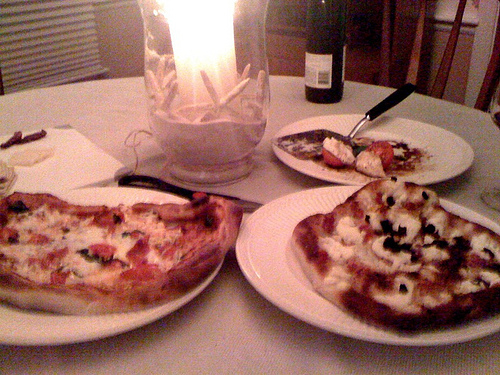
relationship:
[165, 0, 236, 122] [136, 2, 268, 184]
candle in jar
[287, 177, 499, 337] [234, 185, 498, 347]
pizza on plate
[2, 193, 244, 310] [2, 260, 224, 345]
pizza on plate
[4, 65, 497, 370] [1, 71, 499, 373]
table covered with cloth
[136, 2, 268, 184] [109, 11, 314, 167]
jar with starvish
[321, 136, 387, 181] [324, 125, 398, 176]
shells with pastry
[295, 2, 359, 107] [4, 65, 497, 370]
bottle on table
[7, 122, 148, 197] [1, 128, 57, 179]
plate with appetizers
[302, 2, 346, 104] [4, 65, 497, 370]
bottle on table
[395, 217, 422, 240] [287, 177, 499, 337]
feta cheese on pizza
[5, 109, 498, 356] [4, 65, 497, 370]
three plates in table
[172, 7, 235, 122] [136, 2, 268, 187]
candle in jar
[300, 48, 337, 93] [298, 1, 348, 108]
sticker in bottle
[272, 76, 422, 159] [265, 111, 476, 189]
spatula on plate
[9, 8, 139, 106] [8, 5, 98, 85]
blinds on window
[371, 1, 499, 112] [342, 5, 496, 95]
chair has back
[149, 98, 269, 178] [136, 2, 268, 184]
sand in jar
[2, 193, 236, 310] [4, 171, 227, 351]
pizza on plate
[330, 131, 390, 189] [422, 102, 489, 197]
tomato on plate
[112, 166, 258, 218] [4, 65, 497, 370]
scissors on table